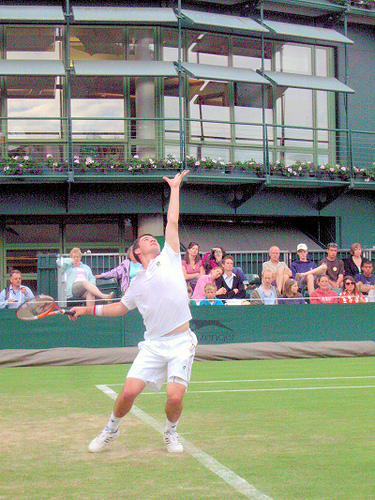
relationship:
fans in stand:
[2, 244, 372, 301] [0, 295, 373, 340]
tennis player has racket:
[13, 164, 201, 474] [16, 293, 82, 328]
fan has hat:
[292, 243, 316, 284] [293, 241, 311, 253]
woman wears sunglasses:
[337, 277, 366, 301] [341, 282, 359, 288]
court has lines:
[1, 356, 373, 498] [188, 370, 374, 396]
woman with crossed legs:
[59, 246, 117, 304] [74, 278, 116, 305]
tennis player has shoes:
[13, 164, 201, 474] [80, 426, 188, 462]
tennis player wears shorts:
[13, 164, 201, 474] [123, 329, 194, 389]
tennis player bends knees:
[13, 164, 201, 474] [113, 384, 192, 405]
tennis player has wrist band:
[13, 164, 201, 474] [94, 301, 105, 317]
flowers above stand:
[5, 149, 374, 190] [0, 295, 373, 340]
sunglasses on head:
[327, 242, 339, 247] [326, 242, 339, 259]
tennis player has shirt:
[13, 164, 201, 474] [120, 243, 197, 331]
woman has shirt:
[337, 277, 366, 301] [342, 291, 367, 306]